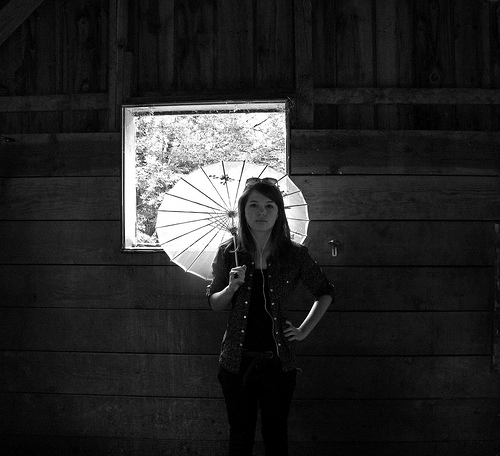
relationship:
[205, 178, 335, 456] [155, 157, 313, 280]
girl holding an umbrella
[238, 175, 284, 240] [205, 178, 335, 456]
head of a girl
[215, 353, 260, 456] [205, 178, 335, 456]
leg of a girl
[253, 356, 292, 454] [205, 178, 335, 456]
leg of a girl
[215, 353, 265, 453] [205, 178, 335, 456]
leg of a girl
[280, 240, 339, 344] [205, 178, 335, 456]
arm of a girl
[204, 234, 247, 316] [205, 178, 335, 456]
arm of a girl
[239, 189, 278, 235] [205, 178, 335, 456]
face of a girl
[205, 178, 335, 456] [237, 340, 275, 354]
girl wears belt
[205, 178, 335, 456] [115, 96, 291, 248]
girl front window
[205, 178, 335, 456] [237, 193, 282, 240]
girl has face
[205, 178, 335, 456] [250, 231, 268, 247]
girl has neck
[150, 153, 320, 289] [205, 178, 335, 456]
parasol behind girl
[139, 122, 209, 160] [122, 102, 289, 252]
trees outside window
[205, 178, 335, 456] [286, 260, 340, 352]
girl has arm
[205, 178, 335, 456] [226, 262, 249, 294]
girl has hand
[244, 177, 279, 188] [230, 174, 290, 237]
sunglasses on head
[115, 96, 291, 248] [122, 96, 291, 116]
window has top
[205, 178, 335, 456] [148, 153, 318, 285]
girl holds umbrella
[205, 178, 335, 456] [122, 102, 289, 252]
girl front window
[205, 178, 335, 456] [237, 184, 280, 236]
girl has face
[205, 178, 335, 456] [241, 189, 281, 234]
girl has face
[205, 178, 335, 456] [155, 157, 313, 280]
girl has umbrella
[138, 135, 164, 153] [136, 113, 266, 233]
leaves on tree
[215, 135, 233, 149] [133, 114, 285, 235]
leaves on tree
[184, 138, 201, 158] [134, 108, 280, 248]
leaves on tree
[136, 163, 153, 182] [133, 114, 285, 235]
leaves on tree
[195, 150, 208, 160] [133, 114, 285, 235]
leaves on tree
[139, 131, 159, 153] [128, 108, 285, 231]
leaves on tree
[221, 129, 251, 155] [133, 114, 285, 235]
leaves on tree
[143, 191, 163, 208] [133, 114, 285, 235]
leaves on tree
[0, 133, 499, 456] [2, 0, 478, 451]
wall on side of a building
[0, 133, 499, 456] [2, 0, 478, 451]
wall on side of building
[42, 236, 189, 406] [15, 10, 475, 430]
wall on side of building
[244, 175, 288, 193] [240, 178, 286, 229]
sunglasses on head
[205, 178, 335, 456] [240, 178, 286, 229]
girl has head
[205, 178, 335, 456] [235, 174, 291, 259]
girl has hair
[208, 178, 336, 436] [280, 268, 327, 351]
girl has arm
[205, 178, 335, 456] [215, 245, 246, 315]
girl has arm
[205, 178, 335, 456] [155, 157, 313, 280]
girl holding umbrella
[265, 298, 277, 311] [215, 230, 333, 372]
button on jacket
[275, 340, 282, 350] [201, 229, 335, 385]
button on jacket